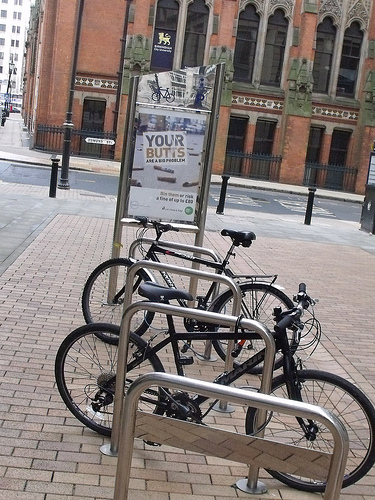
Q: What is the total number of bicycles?
A: 2.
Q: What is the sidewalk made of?
A: Brick.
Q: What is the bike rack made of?
A: Metal.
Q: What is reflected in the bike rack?
A: Brick sidewalk.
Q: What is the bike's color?
A: Black.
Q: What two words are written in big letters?
A: Your Butts.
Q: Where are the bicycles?
A: Parked at the rack.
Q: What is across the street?
A: A building.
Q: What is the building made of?
A: Bricks.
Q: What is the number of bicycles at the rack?
A: Two.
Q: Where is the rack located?
A: On the sidewalk.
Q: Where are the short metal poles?
A: On the edge of the sidewalk.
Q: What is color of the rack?
A: Silver.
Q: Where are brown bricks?
A: On the ground.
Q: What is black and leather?
A: Bicycle seats.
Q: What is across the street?
A: A building.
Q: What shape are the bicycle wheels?
A: Round.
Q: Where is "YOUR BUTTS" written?
A: On a sign.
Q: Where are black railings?
A: In front of a building.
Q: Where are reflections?
A: On silver railings.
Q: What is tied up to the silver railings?
A: Bicycles.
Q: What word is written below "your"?
A: Butts.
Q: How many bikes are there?
A: Two.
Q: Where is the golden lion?
A: On the building.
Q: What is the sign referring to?
A: Cigarettes.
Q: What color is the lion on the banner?
A: Gold.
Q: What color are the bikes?
A: Black.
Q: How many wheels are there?
A: Four.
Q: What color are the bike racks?
A: Silver.